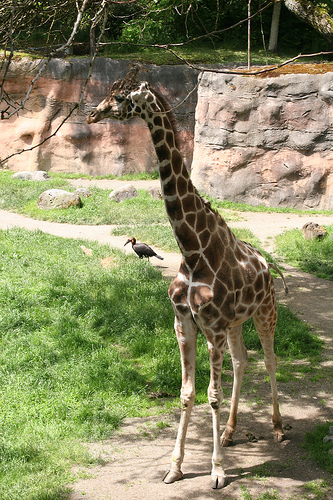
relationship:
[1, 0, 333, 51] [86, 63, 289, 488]
forest behind giraffe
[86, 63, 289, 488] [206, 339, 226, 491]
giraffe has leg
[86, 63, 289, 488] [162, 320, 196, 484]
giraffe has leg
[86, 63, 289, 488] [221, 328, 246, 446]
giraffe has leg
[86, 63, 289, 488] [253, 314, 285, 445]
giraffe has leg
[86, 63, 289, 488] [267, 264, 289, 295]
giraffe has tail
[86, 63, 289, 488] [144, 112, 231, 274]
giraffe has neck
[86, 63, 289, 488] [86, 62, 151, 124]
giraffe has head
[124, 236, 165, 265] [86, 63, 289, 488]
bird behind giraffe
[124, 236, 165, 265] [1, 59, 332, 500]
bird inside pen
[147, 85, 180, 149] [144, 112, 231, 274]
mane growing on neck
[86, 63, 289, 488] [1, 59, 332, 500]
giraffe inside pen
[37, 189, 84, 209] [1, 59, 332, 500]
rock inside pen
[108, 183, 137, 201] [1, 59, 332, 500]
rock inside pen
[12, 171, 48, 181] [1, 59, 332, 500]
rock inside pen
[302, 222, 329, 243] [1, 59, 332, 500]
rock inside pen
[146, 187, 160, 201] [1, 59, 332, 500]
rock inside pen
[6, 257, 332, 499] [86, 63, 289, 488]
shadow behind giraffe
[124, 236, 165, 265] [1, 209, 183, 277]
bird standing on path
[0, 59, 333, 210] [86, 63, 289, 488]
wall behind giraffe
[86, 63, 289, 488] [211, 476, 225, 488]
giraffe has hoof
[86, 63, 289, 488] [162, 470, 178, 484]
giraffe has hoof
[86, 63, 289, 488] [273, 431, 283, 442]
giraffe has hoof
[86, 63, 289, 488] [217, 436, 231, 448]
giraffe has hoof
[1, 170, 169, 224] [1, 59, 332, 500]
grass inside pen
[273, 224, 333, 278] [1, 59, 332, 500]
grass inside pen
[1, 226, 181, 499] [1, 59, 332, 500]
grass inside pen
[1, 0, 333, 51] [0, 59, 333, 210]
forest above wall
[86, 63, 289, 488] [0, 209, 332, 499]
giraffe walking on path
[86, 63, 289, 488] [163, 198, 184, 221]
giraffe has spot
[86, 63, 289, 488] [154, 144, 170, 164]
giraffe has spot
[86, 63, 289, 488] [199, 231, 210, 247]
giraffe has spot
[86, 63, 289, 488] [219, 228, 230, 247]
giraffe has spot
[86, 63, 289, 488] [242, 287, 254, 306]
giraffe has spot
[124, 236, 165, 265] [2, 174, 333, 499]
bird standing on ground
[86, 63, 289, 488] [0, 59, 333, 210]
giraffe in front of wall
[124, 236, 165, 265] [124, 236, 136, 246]
bird has head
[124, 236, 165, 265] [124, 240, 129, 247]
bird has beak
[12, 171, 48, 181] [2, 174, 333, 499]
rock on top of ground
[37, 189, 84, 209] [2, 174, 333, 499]
rock on top of ground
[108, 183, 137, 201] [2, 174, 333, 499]
rock on top of ground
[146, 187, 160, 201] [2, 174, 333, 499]
rock on top of ground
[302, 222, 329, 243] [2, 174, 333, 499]
rock on top of ground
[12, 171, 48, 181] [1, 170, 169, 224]
rock on top of grass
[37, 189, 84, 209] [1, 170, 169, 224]
rock on top of grass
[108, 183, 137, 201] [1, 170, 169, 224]
rock on top of grass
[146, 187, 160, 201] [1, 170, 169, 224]
rock on top of grass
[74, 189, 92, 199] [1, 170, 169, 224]
rock on top of grass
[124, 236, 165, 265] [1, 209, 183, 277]
bird on top of path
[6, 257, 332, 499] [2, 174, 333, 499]
shadow on top of ground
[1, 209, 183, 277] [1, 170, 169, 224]
path next to grass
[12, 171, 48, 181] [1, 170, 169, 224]
rock lying in grass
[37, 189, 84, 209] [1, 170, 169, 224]
rock lying in grass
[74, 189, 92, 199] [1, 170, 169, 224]
rock lying in grass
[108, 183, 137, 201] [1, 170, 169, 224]
rock lying in grass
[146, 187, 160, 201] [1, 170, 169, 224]
rock lying in grass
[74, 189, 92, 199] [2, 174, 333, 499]
rock on top of ground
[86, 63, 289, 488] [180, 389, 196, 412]
giraffe has knee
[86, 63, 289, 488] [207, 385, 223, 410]
giraffe has knee